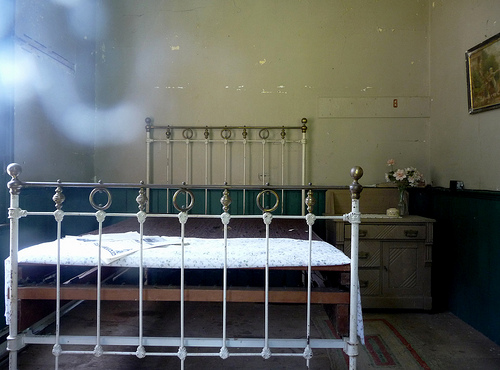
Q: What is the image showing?
A: It is showing a bedroom.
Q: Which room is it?
A: It is a bedroom.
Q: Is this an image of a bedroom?
A: Yes, it is showing a bedroom.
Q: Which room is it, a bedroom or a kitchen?
A: It is a bedroom.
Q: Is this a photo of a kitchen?
A: No, the picture is showing a bedroom.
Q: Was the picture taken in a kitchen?
A: No, the picture was taken in a bedroom.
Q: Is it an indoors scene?
A: Yes, it is indoors.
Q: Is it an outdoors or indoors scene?
A: It is indoors.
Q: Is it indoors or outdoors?
A: It is indoors.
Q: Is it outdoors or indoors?
A: It is indoors.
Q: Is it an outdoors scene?
A: No, it is indoors.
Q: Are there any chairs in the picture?
A: No, there are no chairs.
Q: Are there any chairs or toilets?
A: No, there are no chairs or toilets.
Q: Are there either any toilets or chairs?
A: No, there are no chairs or toilets.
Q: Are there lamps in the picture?
A: No, there are no lamps.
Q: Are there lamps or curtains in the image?
A: No, there are no lamps or curtains.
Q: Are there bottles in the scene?
A: Yes, there is a bottle.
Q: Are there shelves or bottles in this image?
A: Yes, there is a bottle.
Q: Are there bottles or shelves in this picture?
A: Yes, there is a bottle.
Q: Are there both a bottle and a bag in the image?
A: No, there is a bottle but no bags.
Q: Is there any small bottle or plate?
A: Yes, there is a small bottle.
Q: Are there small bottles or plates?
A: Yes, there is a small bottle.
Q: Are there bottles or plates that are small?
A: Yes, the bottle is small.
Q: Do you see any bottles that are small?
A: Yes, there is a small bottle.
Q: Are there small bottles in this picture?
A: Yes, there is a small bottle.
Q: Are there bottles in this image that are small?
A: Yes, there is a bottle that is small.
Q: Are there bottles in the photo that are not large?
A: Yes, there is a small bottle.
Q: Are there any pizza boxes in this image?
A: No, there are no pizza boxes.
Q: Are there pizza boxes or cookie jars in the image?
A: No, there are no pizza boxes or cookie jars.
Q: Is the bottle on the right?
A: Yes, the bottle is on the right of the image.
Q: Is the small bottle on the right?
A: Yes, the bottle is on the right of the image.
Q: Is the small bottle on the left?
A: No, the bottle is on the right of the image.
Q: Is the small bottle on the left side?
A: No, the bottle is on the right of the image.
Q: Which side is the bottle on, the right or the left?
A: The bottle is on the right of the image.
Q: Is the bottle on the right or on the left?
A: The bottle is on the right of the image.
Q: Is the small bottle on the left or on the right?
A: The bottle is on the right of the image.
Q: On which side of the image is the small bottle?
A: The bottle is on the right of the image.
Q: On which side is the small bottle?
A: The bottle is on the right of the image.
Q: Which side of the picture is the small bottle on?
A: The bottle is on the right of the image.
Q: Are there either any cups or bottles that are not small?
A: No, there is a bottle but it is small.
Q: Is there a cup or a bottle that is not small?
A: No, there is a bottle but it is small.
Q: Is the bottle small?
A: Yes, the bottle is small.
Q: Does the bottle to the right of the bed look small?
A: Yes, the bottle is small.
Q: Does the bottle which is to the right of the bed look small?
A: Yes, the bottle is small.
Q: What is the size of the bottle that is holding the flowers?
A: The bottle is small.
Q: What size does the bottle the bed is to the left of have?
A: The bottle has small size.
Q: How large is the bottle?
A: The bottle is small.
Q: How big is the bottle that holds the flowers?
A: The bottle is small.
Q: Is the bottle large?
A: No, the bottle is small.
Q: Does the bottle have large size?
A: No, the bottle is small.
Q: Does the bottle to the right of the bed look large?
A: No, the bottle is small.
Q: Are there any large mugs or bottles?
A: No, there is a bottle but it is small.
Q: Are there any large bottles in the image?
A: No, there is a bottle but it is small.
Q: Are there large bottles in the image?
A: No, there is a bottle but it is small.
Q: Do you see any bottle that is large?
A: No, there is a bottle but it is small.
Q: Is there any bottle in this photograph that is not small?
A: No, there is a bottle but it is small.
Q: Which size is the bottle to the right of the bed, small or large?
A: The bottle is small.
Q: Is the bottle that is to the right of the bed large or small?
A: The bottle is small.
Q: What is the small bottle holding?
A: The bottle is holding the flowers.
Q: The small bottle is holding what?
A: The bottle is holding the flowers.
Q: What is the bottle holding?
A: The bottle is holding the flowers.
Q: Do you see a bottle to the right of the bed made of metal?
A: Yes, there is a bottle to the right of the bed.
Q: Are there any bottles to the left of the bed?
A: No, the bottle is to the right of the bed.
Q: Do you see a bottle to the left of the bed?
A: No, the bottle is to the right of the bed.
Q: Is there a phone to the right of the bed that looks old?
A: No, there is a bottle to the right of the bed.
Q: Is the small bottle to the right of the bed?
A: Yes, the bottle is to the right of the bed.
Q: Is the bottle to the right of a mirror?
A: No, the bottle is to the right of the bed.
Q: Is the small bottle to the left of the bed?
A: No, the bottle is to the right of the bed.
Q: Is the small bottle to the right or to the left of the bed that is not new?
A: The bottle is to the right of the bed.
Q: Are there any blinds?
A: No, there are no blinds.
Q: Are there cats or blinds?
A: No, there are no blinds or cats.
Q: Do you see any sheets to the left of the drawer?
A: Yes, there is a sheet to the left of the drawer.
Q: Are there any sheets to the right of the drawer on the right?
A: No, the sheet is to the left of the drawer.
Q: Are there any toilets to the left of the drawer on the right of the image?
A: No, there is a sheet to the left of the drawer.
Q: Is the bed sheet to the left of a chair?
A: No, the bed sheet is to the left of the drawer.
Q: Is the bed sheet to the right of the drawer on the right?
A: No, the bed sheet is to the left of the drawer.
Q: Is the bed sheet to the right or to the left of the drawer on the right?
A: The bed sheet is to the left of the drawer.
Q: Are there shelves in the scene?
A: No, there are no shelves.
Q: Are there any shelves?
A: No, there are no shelves.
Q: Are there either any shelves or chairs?
A: No, there are no shelves or chairs.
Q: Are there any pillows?
A: No, there are no pillows.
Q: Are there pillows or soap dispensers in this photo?
A: No, there are no pillows or soap dispensers.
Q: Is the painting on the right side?
A: Yes, the painting is on the right of the image.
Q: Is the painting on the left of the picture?
A: No, the painting is on the right of the image.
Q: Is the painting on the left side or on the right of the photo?
A: The painting is on the right of the image.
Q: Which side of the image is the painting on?
A: The painting is on the right of the image.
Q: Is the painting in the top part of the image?
A: Yes, the painting is in the top of the image.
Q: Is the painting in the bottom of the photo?
A: No, the painting is in the top of the image.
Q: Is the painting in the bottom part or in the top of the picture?
A: The painting is in the top of the image.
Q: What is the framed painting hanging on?
A: The painting is hanging on the wall.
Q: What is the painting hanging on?
A: The painting is hanging on the wall.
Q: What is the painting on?
A: The painting is on the wall.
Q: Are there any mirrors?
A: No, there are no mirrors.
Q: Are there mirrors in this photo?
A: No, there are no mirrors.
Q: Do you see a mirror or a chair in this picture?
A: No, there are no mirrors or chairs.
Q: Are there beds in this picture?
A: Yes, there is a bed.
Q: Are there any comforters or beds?
A: Yes, there is a bed.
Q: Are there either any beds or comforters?
A: Yes, there is a bed.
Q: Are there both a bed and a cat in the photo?
A: No, there is a bed but no cats.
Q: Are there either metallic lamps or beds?
A: Yes, there is a metal bed.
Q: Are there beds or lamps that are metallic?
A: Yes, the bed is metallic.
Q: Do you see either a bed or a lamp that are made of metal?
A: Yes, the bed is made of metal.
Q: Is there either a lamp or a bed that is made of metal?
A: Yes, the bed is made of metal.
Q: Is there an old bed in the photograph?
A: Yes, there is an old bed.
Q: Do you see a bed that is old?
A: Yes, there is an old bed.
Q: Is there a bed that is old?
A: Yes, there is a bed that is old.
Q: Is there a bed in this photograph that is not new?
A: Yes, there is a old bed.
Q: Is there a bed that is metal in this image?
A: Yes, there is a metal bed.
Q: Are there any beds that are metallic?
A: Yes, there is a bed that is metallic.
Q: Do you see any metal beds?
A: Yes, there is a bed that is made of metal.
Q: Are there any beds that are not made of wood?
A: Yes, there is a bed that is made of metal.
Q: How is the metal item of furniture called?
A: The piece of furniture is a bed.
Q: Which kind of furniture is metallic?
A: The furniture is a bed.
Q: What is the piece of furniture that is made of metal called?
A: The piece of furniture is a bed.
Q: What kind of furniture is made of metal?
A: The furniture is a bed.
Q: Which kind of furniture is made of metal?
A: The furniture is a bed.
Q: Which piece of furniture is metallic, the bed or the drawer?
A: The bed is metallic.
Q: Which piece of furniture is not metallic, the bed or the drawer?
A: The drawer is not metallic.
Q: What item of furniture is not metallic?
A: The piece of furniture is a drawer.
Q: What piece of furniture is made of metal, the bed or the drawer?
A: The bed is made of metal.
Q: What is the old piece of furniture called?
A: The piece of furniture is a bed.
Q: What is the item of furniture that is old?
A: The piece of furniture is a bed.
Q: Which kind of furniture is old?
A: The furniture is a bed.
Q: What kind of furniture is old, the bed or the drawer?
A: The bed is old.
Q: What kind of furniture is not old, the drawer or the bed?
A: The drawer is not old.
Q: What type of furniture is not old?
A: The furniture is a drawer.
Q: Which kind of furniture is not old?
A: The furniture is a drawer.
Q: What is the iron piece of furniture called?
A: The piece of furniture is a bed.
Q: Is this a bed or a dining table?
A: This is a bed.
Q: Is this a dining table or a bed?
A: This is a bed.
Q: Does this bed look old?
A: Yes, the bed is old.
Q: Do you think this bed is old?
A: Yes, the bed is old.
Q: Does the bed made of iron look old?
A: Yes, the bed is old.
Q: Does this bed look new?
A: No, the bed is old.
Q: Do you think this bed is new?
A: No, the bed is old.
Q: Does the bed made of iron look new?
A: No, the bed is old.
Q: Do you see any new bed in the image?
A: No, there is a bed but it is old.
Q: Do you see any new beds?
A: No, there is a bed but it is old.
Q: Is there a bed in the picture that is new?
A: No, there is a bed but it is old.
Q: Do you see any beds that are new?
A: No, there is a bed but it is old.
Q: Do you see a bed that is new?
A: No, there is a bed but it is old.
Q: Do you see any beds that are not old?
A: No, there is a bed but it is old.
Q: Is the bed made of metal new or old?
A: The bed is old.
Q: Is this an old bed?
A: Yes, this is an old bed.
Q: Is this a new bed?
A: No, this is an old bed.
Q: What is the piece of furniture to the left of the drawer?
A: The piece of furniture is a bed.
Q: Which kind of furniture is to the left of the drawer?
A: The piece of furniture is a bed.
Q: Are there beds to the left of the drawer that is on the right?
A: Yes, there is a bed to the left of the drawer.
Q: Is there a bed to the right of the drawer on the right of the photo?
A: No, the bed is to the left of the drawer.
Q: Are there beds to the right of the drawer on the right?
A: No, the bed is to the left of the drawer.